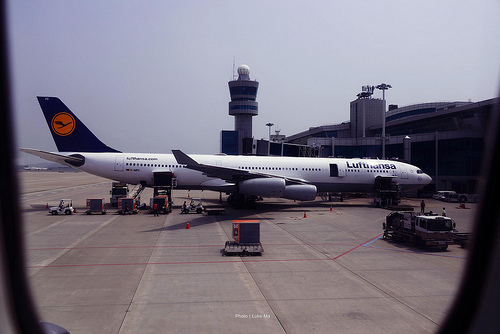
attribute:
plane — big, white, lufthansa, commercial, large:
[45, 89, 451, 211]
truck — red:
[50, 206, 77, 220]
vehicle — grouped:
[383, 209, 452, 264]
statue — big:
[225, 57, 266, 123]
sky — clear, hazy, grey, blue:
[75, 21, 193, 102]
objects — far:
[88, 193, 132, 221]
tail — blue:
[32, 106, 99, 160]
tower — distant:
[226, 56, 253, 160]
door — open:
[323, 160, 348, 187]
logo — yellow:
[51, 119, 82, 136]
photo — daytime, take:
[10, 5, 496, 313]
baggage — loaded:
[159, 177, 167, 192]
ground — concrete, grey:
[74, 230, 163, 308]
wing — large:
[173, 144, 241, 199]